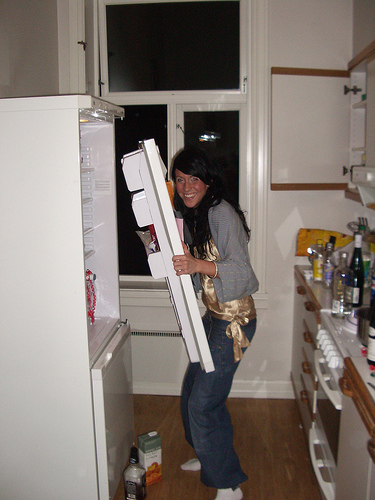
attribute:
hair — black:
[188, 158, 213, 179]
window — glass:
[116, 104, 237, 276]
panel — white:
[166, 103, 183, 180]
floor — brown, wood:
[114, 380, 322, 498]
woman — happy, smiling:
[160, 134, 293, 497]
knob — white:
[326, 357, 339, 370]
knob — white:
[324, 351, 334, 364]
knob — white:
[321, 343, 331, 359]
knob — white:
[320, 340, 329, 352]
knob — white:
[315, 328, 323, 343]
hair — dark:
[171, 143, 251, 258]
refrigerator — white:
[0, 89, 141, 497]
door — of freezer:
[117, 135, 220, 375]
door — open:
[266, 55, 367, 210]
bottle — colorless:
[310, 237, 326, 282]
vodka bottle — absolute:
[332, 247, 354, 318]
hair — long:
[158, 143, 261, 260]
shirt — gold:
[193, 213, 255, 325]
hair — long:
[165, 147, 249, 262]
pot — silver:
[347, 300, 372, 351]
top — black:
[324, 232, 339, 246]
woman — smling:
[169, 140, 252, 497]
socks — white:
[182, 458, 231, 497]